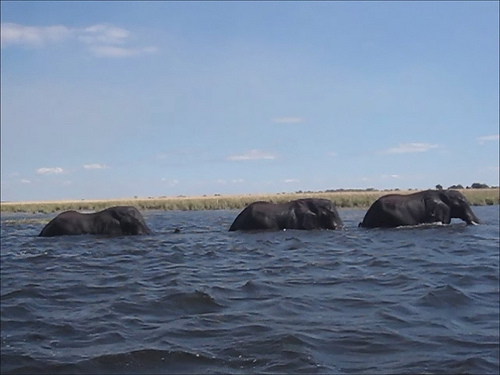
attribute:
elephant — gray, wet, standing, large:
[357, 187, 480, 229]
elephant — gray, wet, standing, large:
[226, 196, 341, 232]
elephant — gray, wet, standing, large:
[37, 206, 179, 237]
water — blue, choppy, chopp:
[1, 205, 498, 371]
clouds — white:
[3, 17, 165, 62]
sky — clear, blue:
[3, 1, 498, 204]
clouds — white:
[17, 161, 114, 187]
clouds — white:
[210, 149, 279, 163]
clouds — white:
[268, 115, 304, 127]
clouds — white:
[366, 139, 441, 159]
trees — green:
[433, 181, 497, 192]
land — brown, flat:
[1, 188, 498, 213]